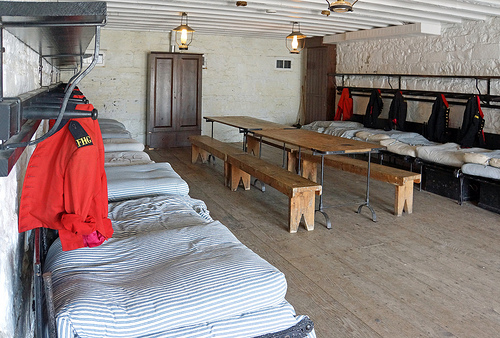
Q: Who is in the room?
A: No one.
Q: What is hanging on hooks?
A: Jackets.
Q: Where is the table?
A: In the middle of the room.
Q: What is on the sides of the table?
A: Benches.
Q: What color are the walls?
A: White.